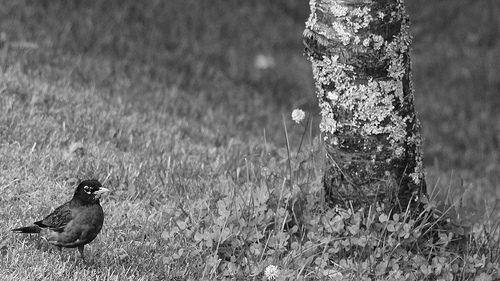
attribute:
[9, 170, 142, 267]
bird — dark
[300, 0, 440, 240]
tree stump — big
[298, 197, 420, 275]
flower leaves — small, green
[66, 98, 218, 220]
grass ground — thick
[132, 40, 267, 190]
grass ground — thick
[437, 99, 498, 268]
grass ground — thick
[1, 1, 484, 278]
grass — thick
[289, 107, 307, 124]
flower blossom — light colored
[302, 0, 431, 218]
tree trunk — light colored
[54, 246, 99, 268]
legs — little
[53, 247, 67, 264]
leg — little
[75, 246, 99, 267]
leg — little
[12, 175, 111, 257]
bird — small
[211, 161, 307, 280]
leaves — small, green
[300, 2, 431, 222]
bark — light colored, black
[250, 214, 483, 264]
grass — freshly cut 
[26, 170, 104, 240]
bird — sitting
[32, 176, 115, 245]
bird — standing 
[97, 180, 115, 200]
beak — sharp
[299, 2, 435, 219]
tree stump — big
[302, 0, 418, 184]
tree stump — big